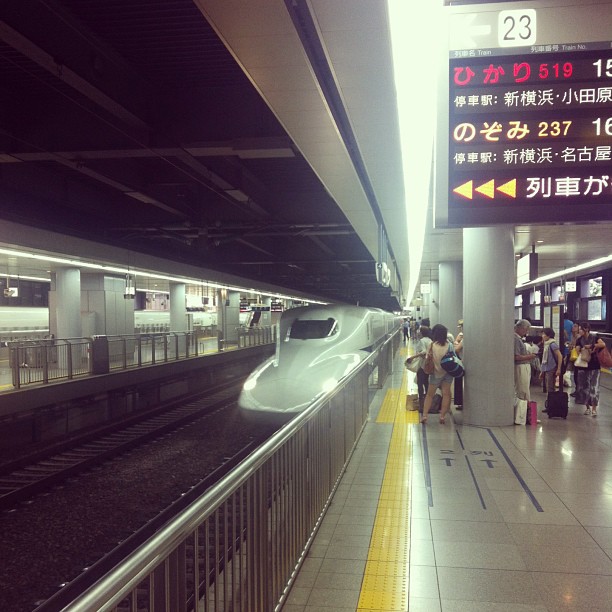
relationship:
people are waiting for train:
[400, 313, 610, 427] [235, 304, 401, 433]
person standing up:
[418, 322, 454, 427] [432, 296, 458, 468]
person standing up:
[537, 322, 567, 417] [398, 329, 451, 484]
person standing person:
[571, 319, 607, 409] [419, 323, 453, 424]